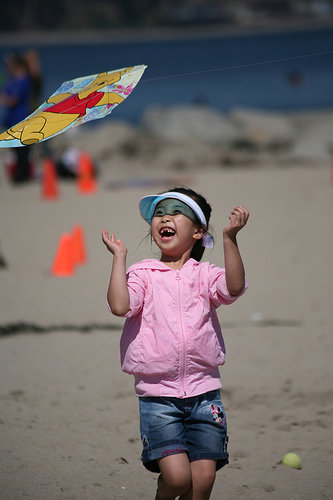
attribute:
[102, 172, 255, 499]
girl — happy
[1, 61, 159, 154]
kite — flying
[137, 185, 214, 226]
visor — white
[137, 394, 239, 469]
shorts — jean, blue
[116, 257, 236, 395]
jacket — pink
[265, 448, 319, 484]
ball — green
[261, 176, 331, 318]
sand — brown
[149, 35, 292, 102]
water — blue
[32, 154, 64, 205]
cone — orange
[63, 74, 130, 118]
character — red, yellow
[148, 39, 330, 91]
string — white